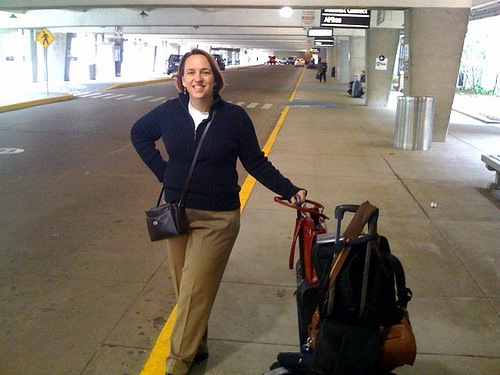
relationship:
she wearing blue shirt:
[118, 43, 315, 366] [125, 93, 290, 207]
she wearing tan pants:
[118, 43, 315, 366] [146, 196, 237, 370]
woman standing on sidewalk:
[126, 47, 315, 370] [189, 57, 483, 372]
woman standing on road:
[126, 51, 303, 364] [2, 63, 314, 370]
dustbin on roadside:
[387, 90, 451, 153] [172, 60, 480, 370]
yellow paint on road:
[264, 105, 282, 167] [2, 63, 314, 370]